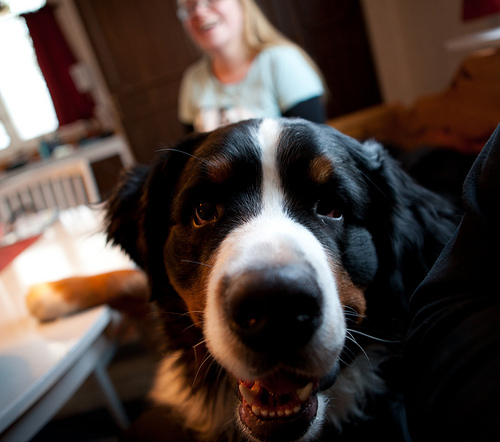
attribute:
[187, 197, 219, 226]
eye — rounded, dark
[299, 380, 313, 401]
canine tooth — pointy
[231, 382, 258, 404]
canine tooth — pointy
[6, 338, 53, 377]
table — white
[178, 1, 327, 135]
woman — straight, blonde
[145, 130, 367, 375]
face — white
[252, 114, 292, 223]
stripe — white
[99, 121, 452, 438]
dog — white and black, happy, black, white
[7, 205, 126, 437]
table — white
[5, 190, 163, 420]
table — white, shiny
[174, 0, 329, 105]
hair — long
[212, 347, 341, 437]
mouth — dog's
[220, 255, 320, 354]
nose — rounded, black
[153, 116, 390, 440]
head — black, white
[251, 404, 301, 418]
teeth — little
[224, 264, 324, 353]
nose — black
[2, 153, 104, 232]
chair — white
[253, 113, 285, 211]
line — white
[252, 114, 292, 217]
line — white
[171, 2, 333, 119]
lady — smiling